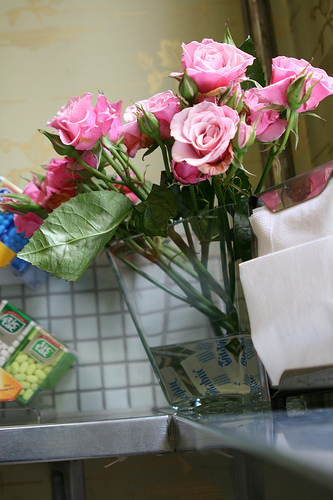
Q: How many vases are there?
A: One.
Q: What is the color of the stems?
A: Green.